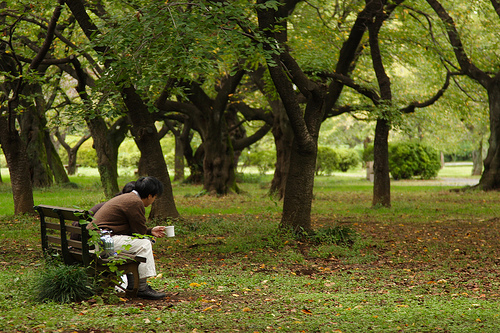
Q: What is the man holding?
A: A cup.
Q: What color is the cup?
A: White.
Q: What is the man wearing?
A: A brown shirt, beige pants, and black shoes.